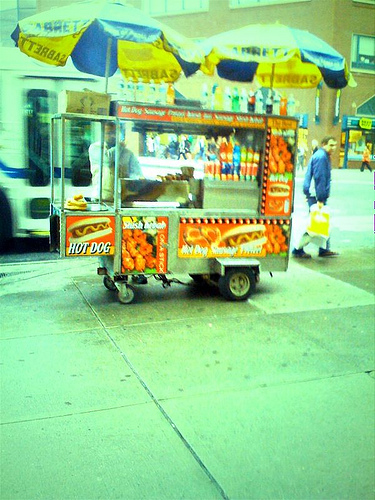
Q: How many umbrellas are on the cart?
A: Two.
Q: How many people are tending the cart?
A: One.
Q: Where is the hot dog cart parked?
A: Sidewalk.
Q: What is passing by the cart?
A: A bus.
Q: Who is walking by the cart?
A: A shopper.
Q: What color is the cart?
A: Orange.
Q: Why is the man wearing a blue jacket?
A: It is a cold day.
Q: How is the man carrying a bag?
A: With his hand.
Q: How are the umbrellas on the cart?
A: Attached to poles.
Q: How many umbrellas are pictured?
A: Two.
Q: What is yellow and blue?
A: Umbrellas.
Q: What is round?
A: Wheels.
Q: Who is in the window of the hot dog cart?
A: Vendor.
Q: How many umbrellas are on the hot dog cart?
A: Two.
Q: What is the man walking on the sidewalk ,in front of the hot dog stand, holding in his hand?
A: Yellow bag.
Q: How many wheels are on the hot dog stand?
A: Four.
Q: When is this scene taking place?
A: Daytime.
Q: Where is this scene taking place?
A: City.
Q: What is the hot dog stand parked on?
A: Sidewalk.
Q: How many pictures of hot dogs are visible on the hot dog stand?
A: Three.